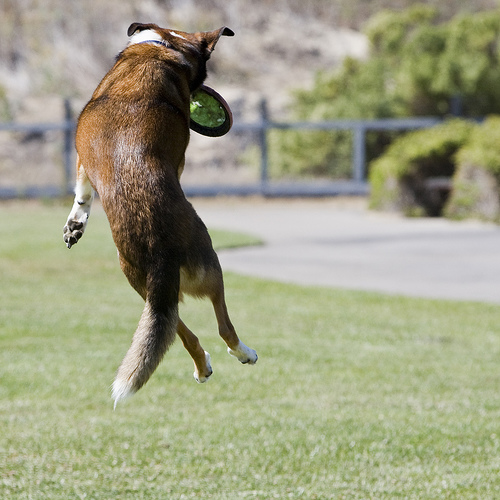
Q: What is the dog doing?
A: Jumping.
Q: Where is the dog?
A: In the air.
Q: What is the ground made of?
A: Grass.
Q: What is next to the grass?
A: The sidewalk.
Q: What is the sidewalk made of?
A: Cement.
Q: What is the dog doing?
A: Catching a frisbee.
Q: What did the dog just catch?
A: A frisbee.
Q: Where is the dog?
A: In the middle of the grass.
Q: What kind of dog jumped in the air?
A: A brown and white dog.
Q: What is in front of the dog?
A: A blue fence.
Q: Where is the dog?
A: In a yard.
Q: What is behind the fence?
A: A tree.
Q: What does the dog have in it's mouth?
A: A frisbee.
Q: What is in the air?
A: A dog.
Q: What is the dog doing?
A: Catching a Frisbee.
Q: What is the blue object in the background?
A: A fence.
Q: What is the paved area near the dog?
A: A walkway.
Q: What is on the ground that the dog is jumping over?
A: Grass.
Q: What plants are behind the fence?
A: Trees.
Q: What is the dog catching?
A: A Frisbee.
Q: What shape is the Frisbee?
A: Round.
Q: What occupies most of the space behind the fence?
A: A hill.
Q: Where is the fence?
A: At the end of the road.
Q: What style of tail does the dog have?
A: Bushy.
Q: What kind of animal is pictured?
A: A dog.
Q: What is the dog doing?
A: Jumping.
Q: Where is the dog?
A: At a park.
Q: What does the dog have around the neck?
A: A collar.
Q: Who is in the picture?
A: A dog.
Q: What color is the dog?
A: Brown and white.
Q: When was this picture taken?
A: During the day.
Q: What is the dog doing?
A: Jumping in the air.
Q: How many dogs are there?
A: One dog.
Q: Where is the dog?
A: At a park.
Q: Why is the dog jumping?
A: Catching a toy.